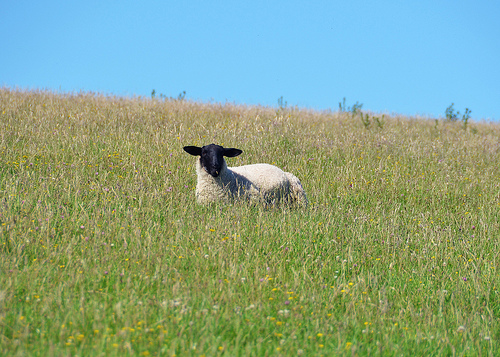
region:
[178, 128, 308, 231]
lone black faced sheep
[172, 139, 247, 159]
ears go out vertically from face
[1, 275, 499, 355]
yellow flowers through the long grass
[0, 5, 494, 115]
bright blue sky with no clouds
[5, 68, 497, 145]
the crest of the hillside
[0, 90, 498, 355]
a long grassed meadow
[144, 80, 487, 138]
tall weeds rise above the grass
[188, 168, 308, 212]
white thick curly fur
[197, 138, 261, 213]
sheep's head throws shadow on the body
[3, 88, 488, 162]
grass is gold on crest of hill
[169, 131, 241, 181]
goat's face is black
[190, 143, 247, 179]
goat's face is black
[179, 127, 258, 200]
goat's face is black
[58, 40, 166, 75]
the sky is clear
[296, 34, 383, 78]
the sky is clear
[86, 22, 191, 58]
the sky is clear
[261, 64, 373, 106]
the sky is clear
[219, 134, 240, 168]
left ear of sheep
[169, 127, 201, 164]
right ear of sheep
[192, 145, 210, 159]
right eye of sheep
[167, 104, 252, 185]
black head of sheep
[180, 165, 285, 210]
white fur of sheep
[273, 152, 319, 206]
back of white sheep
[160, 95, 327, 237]
sheep in the grass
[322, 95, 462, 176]
grass in the background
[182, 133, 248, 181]
face of the sheep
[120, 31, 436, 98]
blue skies in the back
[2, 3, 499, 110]
the bright blue sky above the field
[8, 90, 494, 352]
the tall grass with little flowers all on the hill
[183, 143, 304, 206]
the sheep standing on the hill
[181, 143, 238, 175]
the black face and ears of the sheep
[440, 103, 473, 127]
tall weeds sticking out of the grass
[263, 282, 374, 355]
little yellow and white flowers mixed in with the grass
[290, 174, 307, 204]
the tail of the sheep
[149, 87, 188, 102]
more of the tall weeds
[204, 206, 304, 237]
the grass right next to the sheep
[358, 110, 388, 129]
some more of the tall weeds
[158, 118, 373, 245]
a lone sheep in a field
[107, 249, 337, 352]
the grass is green and has yellow flowers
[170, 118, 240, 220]
the sheep's head is black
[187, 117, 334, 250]
the sheep is sitting in the field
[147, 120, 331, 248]
this is the only animal in the photo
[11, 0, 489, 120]
the sky is clear and blue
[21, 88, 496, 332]
some of the grass is brown and dry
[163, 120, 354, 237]
the sheep is in the middle of the photo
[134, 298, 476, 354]
the flowers are yellow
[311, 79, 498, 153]
there is some larger shrubbery